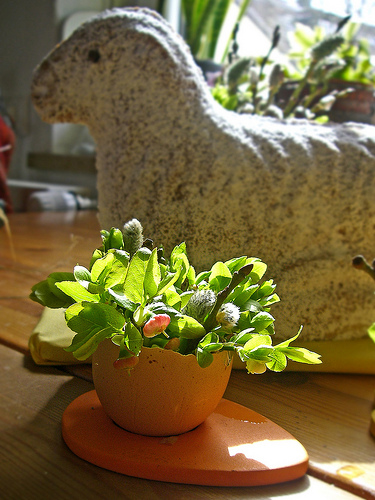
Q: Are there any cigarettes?
A: No, there are no cigarettes.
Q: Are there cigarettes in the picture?
A: No, there are no cigarettes.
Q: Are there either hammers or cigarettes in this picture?
A: No, there are no cigarettes or hammers.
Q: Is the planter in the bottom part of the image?
A: Yes, the planter is in the bottom of the image.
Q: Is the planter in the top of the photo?
A: No, the planter is in the bottom of the image.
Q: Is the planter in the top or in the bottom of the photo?
A: The planter is in the bottom of the image.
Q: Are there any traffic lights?
A: No, there are no traffic lights.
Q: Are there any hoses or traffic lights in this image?
A: No, there are no traffic lights or hoses.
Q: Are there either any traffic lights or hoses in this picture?
A: No, there are no traffic lights or hoses.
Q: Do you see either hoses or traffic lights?
A: No, there are no traffic lights or hoses.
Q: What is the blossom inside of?
A: The blossom is inside the planter.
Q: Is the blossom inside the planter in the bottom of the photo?
A: Yes, the blossom is inside the planter.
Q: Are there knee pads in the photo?
A: No, there are no knee pads.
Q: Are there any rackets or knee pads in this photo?
A: No, there are no knee pads or rackets.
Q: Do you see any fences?
A: No, there are no fences.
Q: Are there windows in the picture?
A: Yes, there is a window.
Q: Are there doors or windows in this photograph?
A: Yes, there is a window.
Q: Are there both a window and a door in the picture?
A: No, there is a window but no doors.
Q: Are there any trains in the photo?
A: No, there are no trains.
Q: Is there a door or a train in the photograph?
A: No, there are no trains or doors.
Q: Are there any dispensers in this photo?
A: No, there are no dispensers.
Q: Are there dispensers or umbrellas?
A: No, there are no dispensers or umbrellas.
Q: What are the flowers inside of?
A: The flowers are inside the planter.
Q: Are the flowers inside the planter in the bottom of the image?
A: Yes, the flowers are inside the planter.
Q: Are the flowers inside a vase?
A: No, the flowers are inside the planter.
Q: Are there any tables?
A: Yes, there is a table.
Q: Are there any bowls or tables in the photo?
A: Yes, there is a table.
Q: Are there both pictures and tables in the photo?
A: No, there is a table but no pictures.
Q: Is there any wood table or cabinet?
A: Yes, there is a wood table.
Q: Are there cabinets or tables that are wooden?
A: Yes, the table is wooden.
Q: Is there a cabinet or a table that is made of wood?
A: Yes, the table is made of wood.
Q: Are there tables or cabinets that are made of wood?
A: Yes, the table is made of wood.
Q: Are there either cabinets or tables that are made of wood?
A: Yes, the table is made of wood.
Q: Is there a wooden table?
A: Yes, there is a wood table.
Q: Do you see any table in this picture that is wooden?
A: Yes, there is a table that is wooden.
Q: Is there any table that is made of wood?
A: Yes, there is a table that is made of wood.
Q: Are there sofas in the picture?
A: No, there are no sofas.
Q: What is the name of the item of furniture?
A: The piece of furniture is a table.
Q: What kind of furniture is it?
A: The piece of furniture is a table.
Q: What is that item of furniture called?
A: This is a table.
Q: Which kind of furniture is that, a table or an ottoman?
A: This is a table.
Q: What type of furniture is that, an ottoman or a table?
A: This is a table.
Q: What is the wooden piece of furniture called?
A: The piece of furniture is a table.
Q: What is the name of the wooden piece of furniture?
A: The piece of furniture is a table.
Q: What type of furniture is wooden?
A: The furniture is a table.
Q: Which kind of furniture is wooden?
A: The furniture is a table.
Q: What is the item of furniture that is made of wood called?
A: The piece of furniture is a table.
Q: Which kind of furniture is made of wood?
A: The furniture is a table.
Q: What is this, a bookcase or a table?
A: This is a table.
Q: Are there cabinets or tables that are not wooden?
A: No, there is a table but it is wooden.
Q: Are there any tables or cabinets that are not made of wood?
A: No, there is a table but it is made of wood.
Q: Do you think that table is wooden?
A: Yes, the table is wooden.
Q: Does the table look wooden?
A: Yes, the table is wooden.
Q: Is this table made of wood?
A: Yes, the table is made of wood.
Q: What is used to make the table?
A: The table is made of wood.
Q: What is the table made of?
A: The table is made of wood.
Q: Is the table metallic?
A: No, the table is wooden.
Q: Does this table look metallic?
A: No, the table is wooden.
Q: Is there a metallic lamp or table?
A: No, there is a table but it is wooden.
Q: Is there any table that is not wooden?
A: No, there is a table but it is wooden.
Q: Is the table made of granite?
A: No, the table is made of wood.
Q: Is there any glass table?
A: No, there is a table but it is made of wood.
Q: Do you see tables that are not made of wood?
A: No, there is a table but it is made of wood.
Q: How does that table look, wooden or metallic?
A: The table is wooden.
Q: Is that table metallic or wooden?
A: The table is wooden.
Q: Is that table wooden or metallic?
A: The table is wooden.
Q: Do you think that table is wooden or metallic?
A: The table is wooden.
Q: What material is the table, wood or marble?
A: The table is made of wood.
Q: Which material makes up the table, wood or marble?
A: The table is made of wood.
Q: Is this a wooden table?
A: Yes, this is a wooden table.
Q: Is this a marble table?
A: No, this is a wooden table.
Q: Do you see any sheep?
A: Yes, there is a sheep.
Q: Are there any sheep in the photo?
A: Yes, there is a sheep.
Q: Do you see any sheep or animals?
A: Yes, there is a sheep.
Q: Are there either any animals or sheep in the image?
A: Yes, there is a sheep.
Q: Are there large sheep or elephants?
A: Yes, there is a large sheep.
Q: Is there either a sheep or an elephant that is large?
A: Yes, the sheep is large.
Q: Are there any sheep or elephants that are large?
A: Yes, the sheep is large.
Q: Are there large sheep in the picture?
A: Yes, there is a large sheep.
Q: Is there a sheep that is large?
A: Yes, there is a sheep that is large.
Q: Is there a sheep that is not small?
A: Yes, there is a large sheep.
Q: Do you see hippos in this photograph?
A: No, there are no hippos.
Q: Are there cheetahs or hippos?
A: No, there are no hippos or cheetahs.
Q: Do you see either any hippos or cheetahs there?
A: No, there are no hippos or cheetahs.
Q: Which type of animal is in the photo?
A: The animal is a sheep.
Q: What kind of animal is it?
A: The animal is a sheep.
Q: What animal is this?
A: This is a sheep.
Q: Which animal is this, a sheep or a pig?
A: This is a sheep.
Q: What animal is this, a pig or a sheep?
A: This is a sheep.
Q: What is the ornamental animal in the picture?
A: The animal is a sheep.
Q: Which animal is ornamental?
A: The animal is a sheep.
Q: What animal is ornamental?
A: The animal is a sheep.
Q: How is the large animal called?
A: The animal is a sheep.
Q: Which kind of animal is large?
A: The animal is a sheep.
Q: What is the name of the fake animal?
A: The animal is a sheep.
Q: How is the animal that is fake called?
A: The animal is a sheep.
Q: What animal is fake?
A: The animal is a sheep.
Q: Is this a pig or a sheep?
A: This is a sheep.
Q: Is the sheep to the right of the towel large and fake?
A: Yes, the sheep is large and fake.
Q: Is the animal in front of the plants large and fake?
A: Yes, the sheep is large and fake.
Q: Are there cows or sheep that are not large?
A: No, there is a sheep but it is large.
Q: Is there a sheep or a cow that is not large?
A: No, there is a sheep but it is large.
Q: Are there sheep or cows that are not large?
A: No, there is a sheep but it is large.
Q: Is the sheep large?
A: Yes, the sheep is large.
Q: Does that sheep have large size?
A: Yes, the sheep is large.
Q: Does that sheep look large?
A: Yes, the sheep is large.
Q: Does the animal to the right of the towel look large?
A: Yes, the sheep is large.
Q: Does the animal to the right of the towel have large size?
A: Yes, the sheep is large.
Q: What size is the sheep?
A: The sheep is large.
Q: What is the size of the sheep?
A: The sheep is large.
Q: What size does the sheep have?
A: The sheep has large size.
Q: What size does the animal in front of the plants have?
A: The sheep has large size.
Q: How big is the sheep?
A: The sheep is large.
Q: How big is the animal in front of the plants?
A: The sheep is large.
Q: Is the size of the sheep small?
A: No, the sheep is large.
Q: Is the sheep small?
A: No, the sheep is large.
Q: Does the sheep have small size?
A: No, the sheep is large.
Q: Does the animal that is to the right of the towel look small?
A: No, the sheep is large.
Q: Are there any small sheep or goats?
A: No, there is a sheep but it is large.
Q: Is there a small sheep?
A: No, there is a sheep but it is large.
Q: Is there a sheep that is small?
A: No, there is a sheep but it is large.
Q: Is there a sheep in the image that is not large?
A: No, there is a sheep but it is large.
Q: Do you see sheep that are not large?
A: No, there is a sheep but it is large.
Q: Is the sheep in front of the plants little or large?
A: The sheep is large.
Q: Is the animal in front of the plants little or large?
A: The sheep is large.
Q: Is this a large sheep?
A: Yes, this is a large sheep.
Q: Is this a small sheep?
A: No, this is a large sheep.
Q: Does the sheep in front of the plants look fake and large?
A: Yes, the sheep is fake and large.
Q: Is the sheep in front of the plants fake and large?
A: Yes, the sheep is fake and large.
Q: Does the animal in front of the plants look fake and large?
A: Yes, the sheep is fake and large.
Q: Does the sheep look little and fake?
A: No, the sheep is fake but large.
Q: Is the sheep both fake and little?
A: No, the sheep is fake but large.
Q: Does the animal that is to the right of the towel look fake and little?
A: No, the sheep is fake but large.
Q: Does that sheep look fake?
A: Yes, the sheep is fake.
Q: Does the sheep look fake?
A: Yes, the sheep is fake.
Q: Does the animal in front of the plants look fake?
A: Yes, the sheep is fake.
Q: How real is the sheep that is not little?
A: The sheep is fake.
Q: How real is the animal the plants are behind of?
A: The sheep is fake.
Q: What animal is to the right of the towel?
A: The animal is a sheep.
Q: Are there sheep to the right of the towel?
A: Yes, there is a sheep to the right of the towel.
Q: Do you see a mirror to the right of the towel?
A: No, there is a sheep to the right of the towel.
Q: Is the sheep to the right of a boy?
A: No, the sheep is to the right of the towel.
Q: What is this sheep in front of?
A: The sheep is in front of the plants.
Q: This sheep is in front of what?
A: The sheep is in front of the plants.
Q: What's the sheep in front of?
A: The sheep is in front of the plants.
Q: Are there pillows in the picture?
A: No, there are no pillows.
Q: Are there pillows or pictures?
A: No, there are no pillows or pictures.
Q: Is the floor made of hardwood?
A: Yes, the floor is made of hardwood.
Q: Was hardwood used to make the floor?
A: Yes, the floor is made of hardwood.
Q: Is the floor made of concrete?
A: No, the floor is made of hardwood.